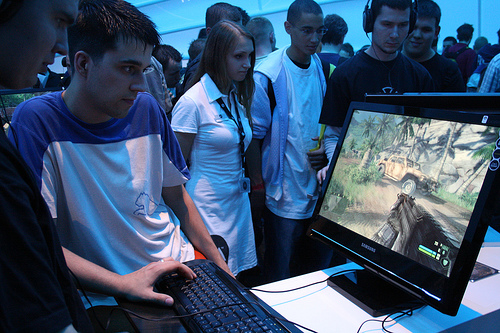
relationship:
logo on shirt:
[128, 186, 175, 226] [11, 76, 211, 301]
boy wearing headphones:
[317, 0, 432, 179] [360, 0, 422, 45]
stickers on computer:
[478, 129, 499, 171] [310, 100, 499, 328]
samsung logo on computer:
[356, 237, 376, 257] [310, 100, 499, 328]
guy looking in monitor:
[45, 3, 212, 287] [321, 98, 493, 302]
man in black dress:
[0, 0, 198, 333] [5, 9, 98, 321]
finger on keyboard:
[167, 250, 195, 281] [162, 241, 275, 331]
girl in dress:
[172, 18, 260, 280] [168, 74, 260, 271]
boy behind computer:
[317, 0, 432, 179] [132, 100, 476, 331]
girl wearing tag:
[172, 18, 260, 280] [210, 82, 254, 194]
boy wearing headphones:
[317, 0, 432, 179] [357, 0, 377, 33]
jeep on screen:
[369, 150, 445, 200] [314, 74, 488, 314]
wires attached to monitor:
[243, 269, 421, 330] [306, 85, 498, 325]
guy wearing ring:
[7, 3, 238, 297] [153, 250, 172, 266]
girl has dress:
[172, 18, 274, 280] [168, 74, 260, 271]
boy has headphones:
[335, 4, 430, 96] [360, 8, 372, 37]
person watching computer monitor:
[411, 3, 441, 85] [351, 79, 498, 126]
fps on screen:
[353, 132, 460, 242] [300, 94, 485, 299]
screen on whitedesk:
[304, 99, 499, 311] [252, 249, 499, 331]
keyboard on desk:
[157, 251, 309, 329] [184, 176, 497, 323]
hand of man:
[117, 254, 195, 310] [135, 253, 214, 311]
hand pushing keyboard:
[117, 254, 195, 310] [157, 259, 277, 327]